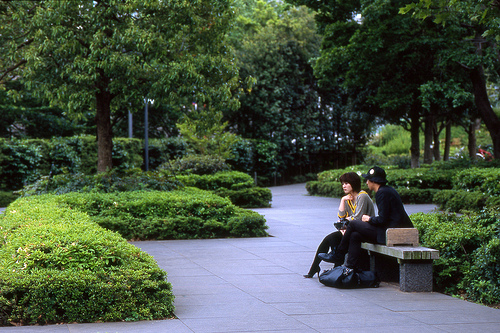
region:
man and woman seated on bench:
[35, 50, 460, 296]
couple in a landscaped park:
[27, 90, 459, 295]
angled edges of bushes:
[65, 150, 285, 322]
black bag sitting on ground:
[302, 215, 413, 292]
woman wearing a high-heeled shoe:
[295, 245, 322, 286]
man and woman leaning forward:
[261, 140, 431, 300]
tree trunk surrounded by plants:
[36, 7, 171, 207]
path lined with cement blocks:
[140, 180, 435, 315]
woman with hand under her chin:
[295, 160, 375, 245]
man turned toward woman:
[300, 157, 430, 294]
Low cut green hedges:
[0, 193, 183, 316]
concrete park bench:
[343, 241, 438, 291]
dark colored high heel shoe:
[304, 264, 320, 278]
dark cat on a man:
[365, 163, 390, 186]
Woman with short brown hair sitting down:
[304, 171, 374, 277]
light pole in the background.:
[137, 89, 159, 178]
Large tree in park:
[0, 0, 236, 177]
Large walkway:
[170, 240, 303, 327]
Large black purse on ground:
[313, 260, 363, 290]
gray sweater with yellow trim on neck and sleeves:
[335, 185, 377, 221]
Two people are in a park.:
[288, 150, 450, 299]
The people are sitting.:
[293, 157, 441, 294]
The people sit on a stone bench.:
[292, 152, 445, 297]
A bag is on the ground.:
[310, 257, 383, 294]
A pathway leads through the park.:
[130, 162, 360, 332]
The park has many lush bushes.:
[0, 168, 262, 331]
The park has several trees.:
[0, 0, 497, 196]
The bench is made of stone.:
[355, 227, 446, 294]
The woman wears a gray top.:
[331, 187, 380, 232]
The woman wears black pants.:
[302, 220, 362, 277]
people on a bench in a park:
[115, 98, 457, 302]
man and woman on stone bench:
[308, 165, 440, 287]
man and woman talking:
[320, 150, 404, 291]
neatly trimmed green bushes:
[19, 159, 279, 315]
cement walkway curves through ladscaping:
[195, 238, 315, 316]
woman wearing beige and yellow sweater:
[325, 171, 370, 230]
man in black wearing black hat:
[355, 161, 420, 228]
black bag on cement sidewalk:
[325, 259, 380, 294]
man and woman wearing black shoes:
[290, 220, 359, 292]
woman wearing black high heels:
[297, 255, 330, 295]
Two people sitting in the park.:
[296, 177, 446, 296]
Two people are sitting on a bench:
[324, 172, 454, 304]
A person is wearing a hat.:
[361, 164, 402, 196]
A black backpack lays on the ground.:
[319, 261, 388, 291]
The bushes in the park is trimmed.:
[31, 184, 233, 316]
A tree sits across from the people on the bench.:
[44, 33, 231, 191]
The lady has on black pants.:
[292, 231, 337, 281]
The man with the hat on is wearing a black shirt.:
[363, 191, 413, 241]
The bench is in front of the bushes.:
[393, 192, 496, 296]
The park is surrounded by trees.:
[48, 31, 499, 174]